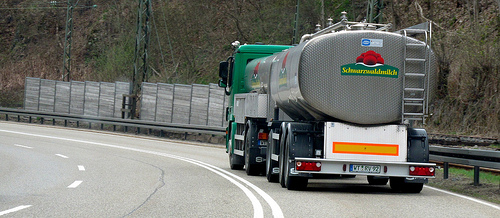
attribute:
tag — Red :
[348, 47, 407, 77]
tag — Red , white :
[293, 152, 437, 179]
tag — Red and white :
[323, 123, 405, 163]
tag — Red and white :
[285, 120, 444, 179]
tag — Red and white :
[322, 118, 415, 166]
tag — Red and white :
[328, 126, 408, 169]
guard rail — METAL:
[438, 126, 479, 183]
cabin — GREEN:
[224, 40, 280, 116]